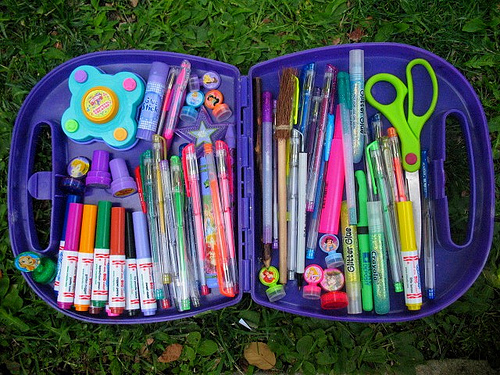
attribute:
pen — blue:
[333, 72, 358, 224]